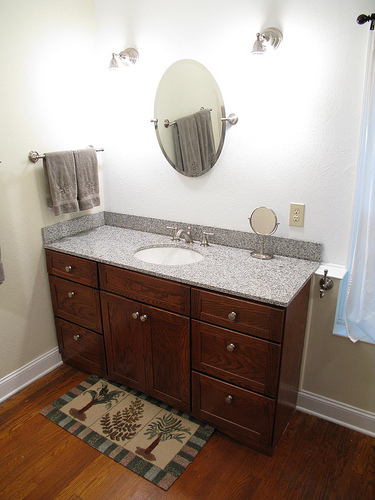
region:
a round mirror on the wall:
[146, 63, 240, 187]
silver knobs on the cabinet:
[227, 306, 239, 369]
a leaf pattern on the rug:
[113, 400, 135, 445]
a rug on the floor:
[76, 382, 184, 453]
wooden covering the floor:
[224, 467, 303, 493]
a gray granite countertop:
[216, 262, 269, 286]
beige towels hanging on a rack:
[43, 154, 113, 215]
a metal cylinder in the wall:
[310, 269, 334, 300]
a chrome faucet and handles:
[169, 227, 210, 245]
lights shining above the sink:
[97, 26, 295, 71]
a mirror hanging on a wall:
[132, 62, 242, 174]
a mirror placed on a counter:
[232, 205, 279, 263]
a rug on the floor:
[17, 428, 238, 479]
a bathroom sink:
[128, 222, 222, 271]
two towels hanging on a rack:
[31, 136, 107, 223]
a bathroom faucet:
[157, 227, 220, 246]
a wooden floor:
[124, 452, 330, 497]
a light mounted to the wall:
[226, 21, 285, 67]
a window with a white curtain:
[310, 117, 372, 365]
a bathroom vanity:
[35, 250, 309, 410]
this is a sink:
[129, 248, 209, 266]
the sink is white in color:
[137, 248, 200, 260]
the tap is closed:
[165, 222, 198, 243]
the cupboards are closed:
[153, 318, 267, 401]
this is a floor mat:
[89, 414, 168, 444]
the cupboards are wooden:
[151, 330, 280, 391]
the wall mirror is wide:
[146, 67, 230, 170]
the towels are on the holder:
[48, 147, 95, 218]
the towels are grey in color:
[54, 156, 89, 198]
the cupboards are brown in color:
[162, 319, 279, 398]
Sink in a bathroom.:
[131, 242, 204, 268]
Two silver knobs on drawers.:
[226, 309, 236, 355]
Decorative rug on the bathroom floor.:
[39, 370, 215, 490]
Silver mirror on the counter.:
[250, 206, 278, 260]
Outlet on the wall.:
[290, 204, 305, 225]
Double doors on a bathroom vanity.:
[96, 290, 190, 415]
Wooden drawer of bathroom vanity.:
[191, 286, 283, 346]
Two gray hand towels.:
[42, 147, 100, 215]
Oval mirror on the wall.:
[153, 57, 227, 177]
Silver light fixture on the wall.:
[109, 46, 136, 67]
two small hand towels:
[24, 141, 105, 226]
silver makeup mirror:
[230, 200, 293, 265]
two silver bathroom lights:
[90, 23, 296, 68]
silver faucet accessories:
[142, 211, 220, 251]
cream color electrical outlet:
[282, 195, 312, 231]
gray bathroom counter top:
[42, 200, 327, 306]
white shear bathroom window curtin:
[324, 129, 369, 348]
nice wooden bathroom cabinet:
[40, 243, 300, 410]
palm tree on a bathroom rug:
[113, 405, 194, 463]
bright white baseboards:
[0, 337, 78, 417]